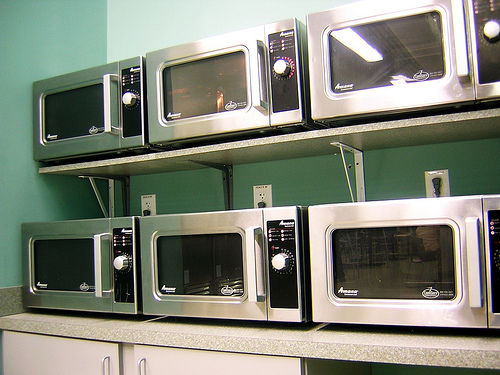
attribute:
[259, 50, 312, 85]
red numbers — red 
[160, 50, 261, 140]
light — on 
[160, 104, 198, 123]
white letters — white 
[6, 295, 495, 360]
counter — gray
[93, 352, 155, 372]
cabinet handles — silver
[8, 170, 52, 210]
green paint — green 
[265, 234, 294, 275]
silver knob — Silver 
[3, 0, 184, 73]
wall — green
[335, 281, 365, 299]
white writing — White 